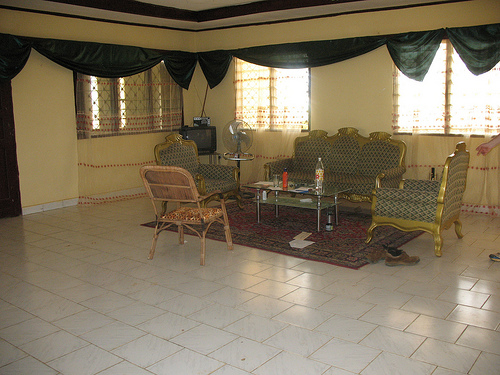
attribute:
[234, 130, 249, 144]
blades — metal 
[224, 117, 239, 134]
blades — metal 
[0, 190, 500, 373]
floor — white, tiled, dirty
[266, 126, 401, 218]
couch — gold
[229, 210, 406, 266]
rug — red 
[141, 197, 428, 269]
rug — red 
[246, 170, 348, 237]
coffee table — glass 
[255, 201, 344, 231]
legs — silver 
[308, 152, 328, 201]
bottle — plastic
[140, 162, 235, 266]
chair — brown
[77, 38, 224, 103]
black drapes — black 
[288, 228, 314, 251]
white papers — white 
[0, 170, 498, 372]
floor — tiled 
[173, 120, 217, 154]
television — small, black